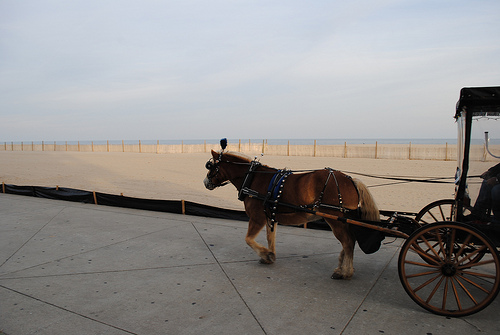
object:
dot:
[254, 289, 264, 296]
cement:
[0, 189, 499, 334]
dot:
[208, 241, 216, 247]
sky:
[2, 2, 499, 148]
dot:
[189, 300, 199, 308]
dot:
[86, 257, 94, 264]